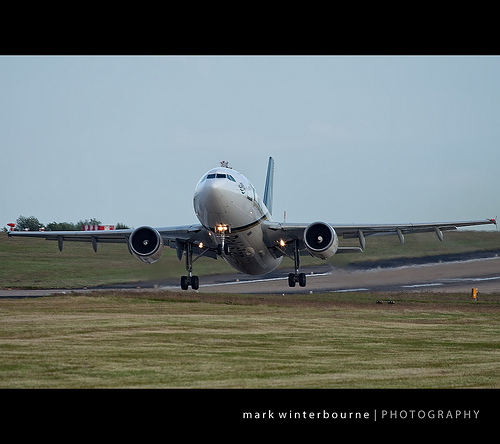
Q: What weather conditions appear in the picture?
A: It is cloudy.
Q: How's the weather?
A: It is cloudy.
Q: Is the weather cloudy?
A: Yes, it is cloudy.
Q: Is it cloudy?
A: Yes, it is cloudy.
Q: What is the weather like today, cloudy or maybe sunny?
A: It is cloudy.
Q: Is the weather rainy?
A: No, it is cloudy.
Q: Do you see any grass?
A: Yes, there is grass.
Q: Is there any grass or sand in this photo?
A: Yes, there is grass.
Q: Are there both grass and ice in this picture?
A: No, there is grass but no ice.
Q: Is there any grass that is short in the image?
A: Yes, there is short grass.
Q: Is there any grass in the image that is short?
A: Yes, there is grass that is short.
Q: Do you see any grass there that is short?
A: Yes, there is grass that is short.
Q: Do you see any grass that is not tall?
A: Yes, there is short grass.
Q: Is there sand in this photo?
A: No, there is no sand.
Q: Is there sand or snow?
A: No, there are no sand or snow.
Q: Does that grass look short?
A: Yes, the grass is short.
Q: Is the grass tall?
A: No, the grass is short.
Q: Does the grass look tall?
A: No, the grass is short.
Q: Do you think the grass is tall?
A: No, the grass is short.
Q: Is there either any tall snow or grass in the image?
A: No, there is grass but it is short.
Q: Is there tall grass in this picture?
A: No, there is grass but it is short.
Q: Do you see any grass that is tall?
A: No, there is grass but it is short.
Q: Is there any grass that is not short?
A: No, there is grass but it is short.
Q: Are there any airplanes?
A: Yes, there is an airplane.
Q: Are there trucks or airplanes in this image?
A: Yes, there is an airplane.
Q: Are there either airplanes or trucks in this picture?
A: Yes, there is an airplane.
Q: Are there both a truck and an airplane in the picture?
A: No, there is an airplane but no trucks.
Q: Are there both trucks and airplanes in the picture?
A: No, there is an airplane but no trucks.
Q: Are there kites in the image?
A: No, there are no kites.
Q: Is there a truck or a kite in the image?
A: No, there are no kites or trucks.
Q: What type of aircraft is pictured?
A: The aircraft is an airplane.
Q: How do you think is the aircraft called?
A: The aircraft is an airplane.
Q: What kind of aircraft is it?
A: The aircraft is an airplane.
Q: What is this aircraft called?
A: This is an airplane.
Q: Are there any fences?
A: No, there are no fences.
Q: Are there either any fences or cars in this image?
A: No, there are no fences or cars.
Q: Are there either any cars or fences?
A: No, there are no fences or cars.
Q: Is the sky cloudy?
A: Yes, the sky is cloudy.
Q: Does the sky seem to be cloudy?
A: Yes, the sky is cloudy.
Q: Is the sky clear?
A: No, the sky is cloudy.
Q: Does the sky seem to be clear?
A: No, the sky is cloudy.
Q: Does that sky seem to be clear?
A: No, the sky is cloudy.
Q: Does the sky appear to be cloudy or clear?
A: The sky is cloudy.